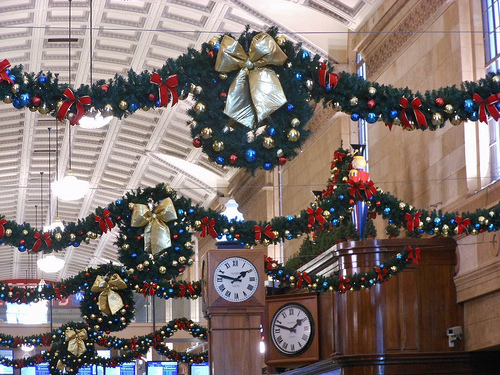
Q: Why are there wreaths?
A: It is a holiday.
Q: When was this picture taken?
A: At 2:47.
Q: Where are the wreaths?
A: In the room, overhead.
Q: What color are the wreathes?
A: Green.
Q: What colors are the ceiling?
A: White and gray.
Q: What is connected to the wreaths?
A: Decorations.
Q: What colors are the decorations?
A: Red, gold and blue.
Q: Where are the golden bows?
A: On the wreaths.